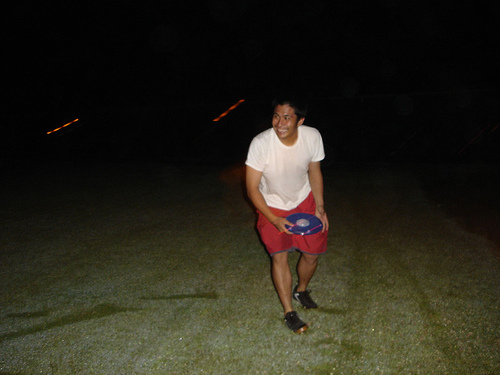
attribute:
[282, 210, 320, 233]
frisbee — purple 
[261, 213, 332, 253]
shorts — red 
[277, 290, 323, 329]
shoes — black 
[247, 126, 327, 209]
shirt — white 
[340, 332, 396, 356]
turf — green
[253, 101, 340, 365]
man — smiling 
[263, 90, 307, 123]
hair — black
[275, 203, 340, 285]
frisbee — blue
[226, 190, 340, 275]
shorts — red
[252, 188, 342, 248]
frisbee — blue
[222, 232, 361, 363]
shoes — athletic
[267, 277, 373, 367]
shoes — black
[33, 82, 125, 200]
lights — orange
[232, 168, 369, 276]
shorts — pink 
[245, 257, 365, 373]
shoes — black 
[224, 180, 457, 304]
shorts — red 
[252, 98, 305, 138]
face — smile, man's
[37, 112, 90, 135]
lights — stripe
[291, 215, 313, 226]
circle — white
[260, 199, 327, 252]
shorts — red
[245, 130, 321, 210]
shirt — white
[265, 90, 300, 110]
hair — black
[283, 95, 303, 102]
hair — black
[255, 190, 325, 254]
shorts — red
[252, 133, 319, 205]
shirt — white